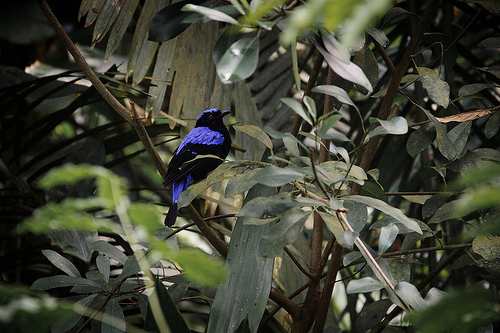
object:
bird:
[159, 108, 234, 227]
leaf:
[90, 295, 130, 331]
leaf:
[213, 157, 298, 206]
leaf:
[370, 110, 411, 140]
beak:
[220, 110, 232, 118]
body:
[166, 125, 231, 184]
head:
[196, 108, 231, 128]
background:
[0, 0, 499, 332]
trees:
[36, 5, 470, 330]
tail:
[164, 182, 183, 226]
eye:
[208, 114, 214, 119]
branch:
[61, 28, 302, 315]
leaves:
[22, 174, 292, 329]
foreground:
[3, 191, 270, 330]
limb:
[149, 152, 201, 227]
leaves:
[294, 164, 477, 276]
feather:
[165, 207, 177, 225]